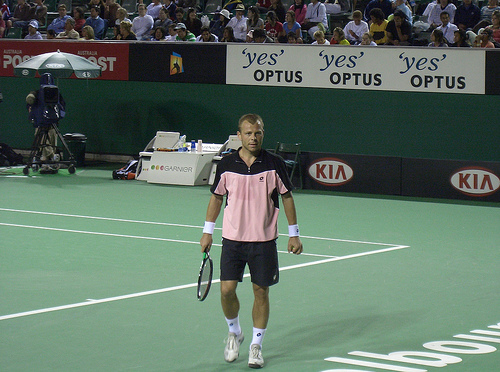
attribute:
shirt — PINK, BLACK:
[208, 151, 294, 243]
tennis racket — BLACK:
[192, 255, 217, 305]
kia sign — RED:
[3, 138, 494, 205]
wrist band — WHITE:
[197, 220, 217, 235]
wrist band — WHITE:
[286, 224, 299, 237]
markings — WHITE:
[3, 203, 407, 319]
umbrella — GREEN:
[19, 49, 103, 73]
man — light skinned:
[196, 115, 303, 364]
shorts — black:
[220, 237, 281, 285]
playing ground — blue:
[3, 164, 494, 366]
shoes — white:
[216, 330, 277, 366]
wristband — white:
[273, 215, 336, 261]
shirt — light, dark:
[215, 155, 302, 250]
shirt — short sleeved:
[194, 140, 320, 254]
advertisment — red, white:
[303, 153, 398, 206]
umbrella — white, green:
[2, 41, 146, 105]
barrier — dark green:
[45, 81, 459, 176]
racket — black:
[172, 238, 241, 321]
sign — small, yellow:
[149, 35, 219, 93]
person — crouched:
[1, 92, 81, 161]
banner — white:
[224, 38, 488, 107]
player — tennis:
[178, 96, 317, 359]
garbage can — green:
[37, 120, 107, 181]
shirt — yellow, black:
[358, 13, 401, 52]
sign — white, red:
[301, 150, 374, 190]